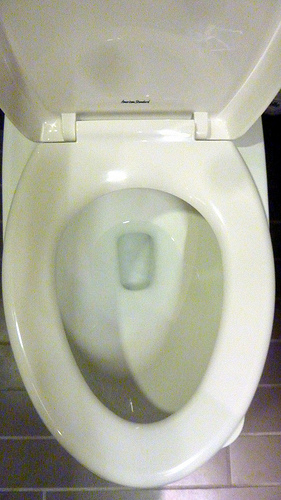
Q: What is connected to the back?
A: A lid.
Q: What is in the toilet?
A: Water.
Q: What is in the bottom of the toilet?
A: Hole.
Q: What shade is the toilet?
A: White.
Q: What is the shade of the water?
A: Clear.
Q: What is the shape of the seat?
A: Oval.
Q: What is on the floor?
A: Tile.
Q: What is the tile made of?
A: Vinyl.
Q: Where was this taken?
A: A bathroom.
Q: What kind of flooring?
A: Tiles.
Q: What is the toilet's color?
A: White.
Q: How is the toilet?
A: The lid is open.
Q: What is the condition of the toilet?
A: Clean.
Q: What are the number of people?
A: Zero.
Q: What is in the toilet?
A: Nothing.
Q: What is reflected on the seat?
A: The light.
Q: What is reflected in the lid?
A: The reflection of the seat.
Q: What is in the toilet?
A: Water.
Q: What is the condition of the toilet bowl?
A: It is stained.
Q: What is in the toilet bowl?
A: Water.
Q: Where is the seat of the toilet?
A: Down.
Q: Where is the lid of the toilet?
A: Up.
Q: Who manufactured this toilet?
A: American Standard.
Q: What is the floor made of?
A: Dark tiles.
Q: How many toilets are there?
A: One.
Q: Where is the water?
A: In the bowl.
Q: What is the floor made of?
A: Tile.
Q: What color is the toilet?
A: White.